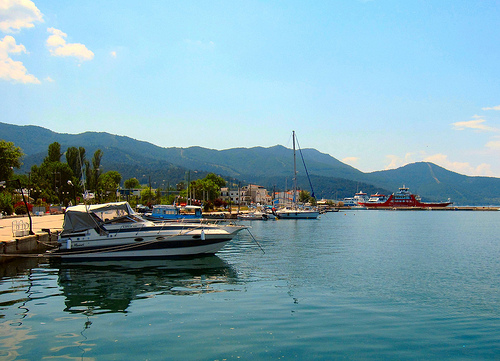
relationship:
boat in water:
[36, 200, 251, 263] [165, 212, 440, 356]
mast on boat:
[282, 123, 322, 188] [238, 118, 336, 227]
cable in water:
[213, 204, 292, 244] [141, 235, 401, 344]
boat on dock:
[36, 200, 251, 263] [2, 221, 96, 286]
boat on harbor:
[36, 200, 251, 263] [0, 203, 499, 258]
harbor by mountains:
[26, 180, 480, 349] [20, 129, 341, 219]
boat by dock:
[36, 200, 251, 263] [17, 188, 105, 267]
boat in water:
[36, 200, 251, 263] [12, 210, 494, 355]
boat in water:
[48, 200, 250, 259] [12, 210, 494, 355]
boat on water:
[36, 200, 251, 263] [12, 210, 494, 355]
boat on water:
[146, 200, 207, 225] [12, 210, 494, 355]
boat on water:
[268, 130, 323, 220] [12, 210, 494, 355]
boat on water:
[273, 130, 321, 219] [12, 210, 494, 355]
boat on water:
[358, 185, 449, 212] [12, 210, 494, 355]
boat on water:
[36, 200, 251, 263] [2, 201, 499, 358]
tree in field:
[0, 138, 27, 189] [3, 143, 120, 215]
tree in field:
[38, 161, 74, 200] [2, 140, 133, 209]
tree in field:
[47, 141, 62, 163] [2, 139, 147, 211]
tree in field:
[66, 146, 81, 178] [2, 140, 133, 209]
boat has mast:
[273, 130, 321, 219] [289, 129, 298, 210]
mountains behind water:
[0, 121, 498, 206] [12, 210, 494, 355]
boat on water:
[355, 183, 455, 211] [12, 210, 494, 355]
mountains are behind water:
[0, 121, 498, 206] [129, 220, 491, 343]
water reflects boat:
[48, 278, 260, 359] [37, 199, 247, 279]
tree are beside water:
[0, 138, 27, 189] [49, 247, 490, 346]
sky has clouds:
[97, 15, 392, 110] [5, 3, 96, 96]